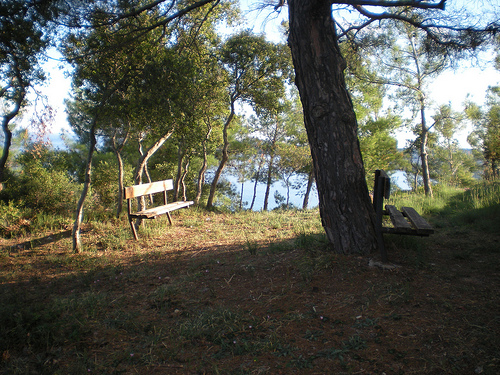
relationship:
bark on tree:
[315, 49, 341, 168] [279, 12, 373, 260]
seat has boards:
[109, 163, 191, 270] [127, 201, 184, 223]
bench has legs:
[124, 173, 187, 229] [136, 216, 169, 237]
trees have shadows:
[81, 26, 296, 178] [23, 212, 486, 366]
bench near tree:
[368, 170, 428, 251] [279, 12, 373, 260]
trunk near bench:
[302, 37, 376, 243] [368, 170, 428, 251]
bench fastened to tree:
[368, 170, 428, 251] [279, 12, 373, 260]